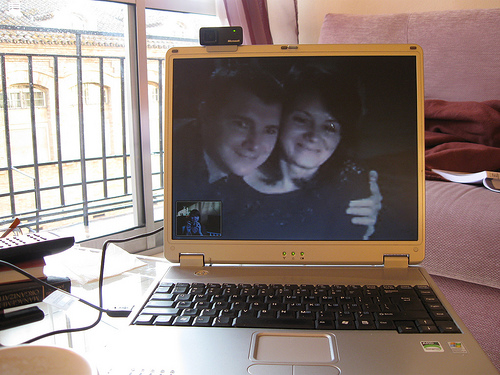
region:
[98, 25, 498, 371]
laptop computer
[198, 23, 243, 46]
webcam attached to top of laptop computer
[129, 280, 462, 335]
keyboard on laptop computer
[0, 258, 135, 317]
USB cable attached to laptop computer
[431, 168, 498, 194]
a book with its pages opened, turned face down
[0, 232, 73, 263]
remote control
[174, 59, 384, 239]
a man and a woman embracing and smiling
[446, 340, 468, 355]
Microsoft Windows logo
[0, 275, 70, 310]
book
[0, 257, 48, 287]
book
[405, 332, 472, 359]
stickers on the laptop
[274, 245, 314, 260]
lights on the laptop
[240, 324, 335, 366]
trackpad on the laptop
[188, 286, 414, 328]
keys on the keyboard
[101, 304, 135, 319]
drive on the laptop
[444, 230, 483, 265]
the couch is pink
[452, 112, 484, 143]
the blanket is red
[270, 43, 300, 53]
logo of the laptop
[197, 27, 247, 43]
webcam for the laptop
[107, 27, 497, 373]
A silver laptop with a black camera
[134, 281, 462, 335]
A black keyboard on a laptop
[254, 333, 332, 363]
A touch pad on a laptop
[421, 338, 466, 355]
Two stickers on a laptop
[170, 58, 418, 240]
Computer screen on a laptop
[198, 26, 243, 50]
A black camera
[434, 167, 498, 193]
A book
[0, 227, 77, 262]
A remote controller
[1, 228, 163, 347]
A black cable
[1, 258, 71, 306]
Books under a remote controller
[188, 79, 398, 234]
a picture of a couple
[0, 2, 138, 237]
a window in a room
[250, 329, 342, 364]
the touch pad of a laptop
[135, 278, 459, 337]
the keyboard of a laptop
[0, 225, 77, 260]
a TV remote control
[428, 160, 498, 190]
an opened book on a bed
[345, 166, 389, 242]
the hand of a person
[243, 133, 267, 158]
the nose of a man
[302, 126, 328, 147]
the nose of a woman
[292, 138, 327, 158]
the mouth of a woman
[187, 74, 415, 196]
Two people on the majority of the monitor.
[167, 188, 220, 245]
Little girl on the bottom of the screen.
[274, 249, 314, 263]
Lights on the monitor.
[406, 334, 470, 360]
Stickers on the laptop.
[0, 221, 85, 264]
Remote on a stack of books.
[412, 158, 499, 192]
Book on the sofa.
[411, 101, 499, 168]
Blanket on the sofa.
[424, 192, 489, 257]
The sofa is pink.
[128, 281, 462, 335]
The keys are black.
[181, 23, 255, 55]
Webcam mounted on the laptop.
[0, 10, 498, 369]
Office and sleeping area with window and view.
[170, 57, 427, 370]
Silver laptop with screensaver.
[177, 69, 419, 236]
Smiling couple and smaller photo of child on screen.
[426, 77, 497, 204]
Sleeping area with rumpled bedding and open book.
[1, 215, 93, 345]
Wire, remote and piled books.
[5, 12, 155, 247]
Uncovered, silver-framed window.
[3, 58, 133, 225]
Black terrace fencing, outside window.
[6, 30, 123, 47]
Curved, red tiling on roof, outside window.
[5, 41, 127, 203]
Sand-colored building, outside window, with arched windows.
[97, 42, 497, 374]
an open laptop computer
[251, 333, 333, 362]
a computer track pad